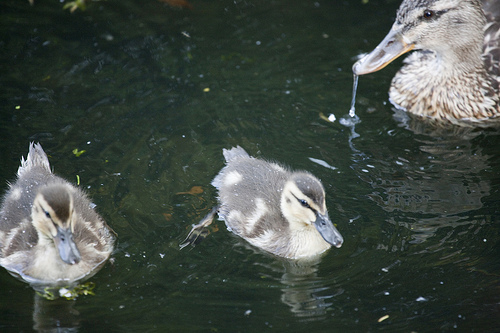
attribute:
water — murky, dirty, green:
[0, 4, 498, 331]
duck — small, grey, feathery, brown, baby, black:
[208, 142, 348, 262]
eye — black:
[294, 198, 313, 213]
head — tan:
[279, 170, 348, 249]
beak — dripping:
[347, 36, 414, 123]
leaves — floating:
[29, 1, 95, 14]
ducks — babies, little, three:
[0, 140, 346, 283]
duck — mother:
[353, 1, 500, 129]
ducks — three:
[0, 1, 500, 285]